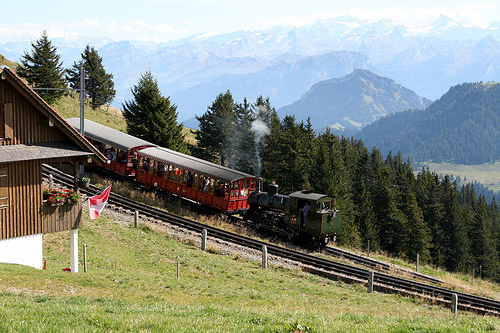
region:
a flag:
[86, 185, 117, 217]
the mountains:
[226, 33, 323, 93]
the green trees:
[346, 172, 453, 245]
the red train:
[122, 152, 284, 207]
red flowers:
[41, 186, 73, 205]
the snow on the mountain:
[250, 15, 449, 40]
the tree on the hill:
[21, 36, 68, 82]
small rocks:
[223, 244, 244, 253]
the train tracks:
[326, 245, 348, 264]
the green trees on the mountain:
[411, 107, 476, 147]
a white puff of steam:
[248, 112, 273, 181]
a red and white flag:
[82, 186, 114, 221]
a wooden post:
[261, 243, 269, 265]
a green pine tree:
[68, 43, 113, 110]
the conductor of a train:
[297, 197, 313, 227]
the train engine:
[238, 172, 338, 250]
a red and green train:
[62, 109, 340, 253]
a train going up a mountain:
[51, 101, 353, 258]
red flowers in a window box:
[40, 185, 78, 206]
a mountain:
[283, 65, 432, 135]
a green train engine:
[243, 178, 339, 248]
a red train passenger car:
[136, 143, 256, 221]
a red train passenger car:
[60, 115, 153, 187]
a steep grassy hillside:
[0, 56, 499, 331]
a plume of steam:
[248, 117, 268, 185]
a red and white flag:
[90, 185, 110, 220]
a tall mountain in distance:
[274, 68, 435, 143]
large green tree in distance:
[124, 68, 187, 156]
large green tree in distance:
[69, 42, 116, 112]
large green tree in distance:
[17, 30, 72, 106]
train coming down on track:
[53, 87, 333, 242]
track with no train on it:
[57, 229, 483, 301]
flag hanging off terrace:
[85, 182, 108, 217]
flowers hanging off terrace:
[41, 183, 81, 206]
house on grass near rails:
[3, 148, 95, 275]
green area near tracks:
[35, 240, 303, 329]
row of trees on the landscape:
[225, 88, 488, 256]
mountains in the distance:
[131, 19, 435, 97]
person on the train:
[296, 198, 311, 228]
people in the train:
[134, 160, 249, 195]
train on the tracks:
[53, 102, 328, 280]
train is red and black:
[58, 103, 315, 272]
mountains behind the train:
[107, 15, 467, 164]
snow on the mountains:
[208, 9, 446, 59]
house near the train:
[8, 73, 113, 315]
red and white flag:
[83, 178, 139, 230]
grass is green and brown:
[130, 259, 267, 331]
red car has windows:
[137, 155, 217, 200]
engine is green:
[243, 180, 351, 235]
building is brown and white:
[6, 140, 111, 300]